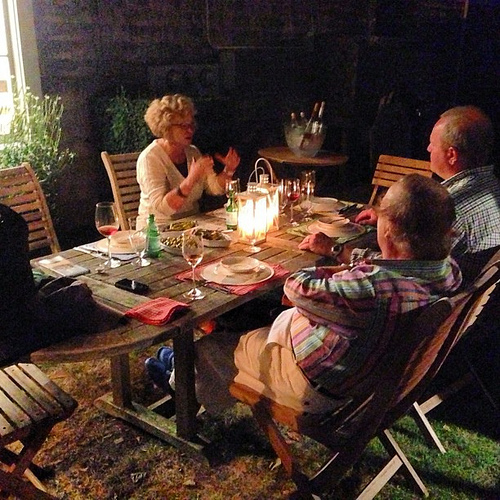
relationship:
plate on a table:
[206, 252, 308, 290] [17, 190, 404, 469]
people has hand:
[135, 93, 242, 232] [210, 145, 242, 169]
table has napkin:
[30, 191, 377, 361] [123, 295, 188, 323]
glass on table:
[179, 229, 206, 298] [87, 217, 267, 302]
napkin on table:
[123, 297, 188, 336] [62, 185, 231, 351]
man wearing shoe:
[144, 173, 457, 478] [143, 355, 171, 398]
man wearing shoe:
[144, 173, 457, 478] [158, 341, 179, 372]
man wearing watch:
[298, 103, 498, 270] [328, 241, 342, 258]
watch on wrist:
[328, 241, 342, 258] [327, 236, 347, 261]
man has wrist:
[298, 103, 498, 270] [327, 236, 347, 261]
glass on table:
[238, 175, 296, 239] [29, 180, 380, 462]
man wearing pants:
[144, 173, 457, 478] [169, 314, 350, 421]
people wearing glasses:
[135, 93, 242, 232] [168, 116, 199, 132]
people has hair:
[135, 93, 242, 232] [146, 95, 198, 125]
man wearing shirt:
[298, 103, 498, 270] [437, 162, 499, 267]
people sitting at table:
[80, 77, 487, 422] [29, 180, 380, 462]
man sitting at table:
[144, 173, 457, 478] [29, 180, 380, 462]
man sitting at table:
[298, 103, 498, 270] [29, 180, 380, 462]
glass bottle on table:
[141, 210, 162, 258] [29, 180, 380, 462]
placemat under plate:
[172, 250, 294, 298] [199, 250, 275, 290]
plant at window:
[4, 90, 69, 168] [0, 0, 50, 159]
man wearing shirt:
[144, 173, 457, 478] [283, 255, 463, 402]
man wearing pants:
[144, 173, 457, 478] [169, 306, 344, 417]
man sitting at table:
[178, 156, 455, 477] [29, 180, 380, 462]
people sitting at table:
[135, 93, 242, 232] [16, 195, 377, 455]